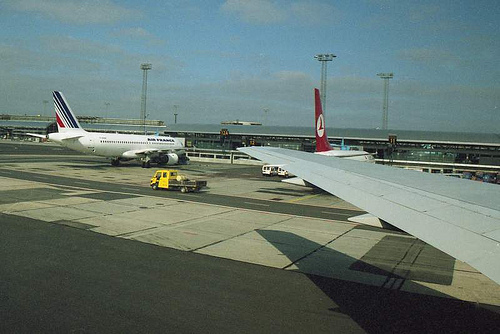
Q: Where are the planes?
A: On the runway.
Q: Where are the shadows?
A: On the ground.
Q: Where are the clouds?
A: In the sky.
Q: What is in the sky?
A: Clouds.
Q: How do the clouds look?
A: Grey.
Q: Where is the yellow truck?
A: Between the planes.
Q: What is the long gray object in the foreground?
A: Wing of airplane.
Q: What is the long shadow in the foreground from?
A: Wing of airplane.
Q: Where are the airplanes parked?
A: Tarmac.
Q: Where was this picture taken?
A: Airport.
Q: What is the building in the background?
A: Airport Terminal.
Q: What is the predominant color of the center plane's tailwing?
A: Red.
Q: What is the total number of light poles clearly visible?
A: 3.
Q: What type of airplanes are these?
A: Passenger Jets.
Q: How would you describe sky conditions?
A: Clear with some clouds.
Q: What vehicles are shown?
A: Airplanes.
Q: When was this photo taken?
A: Daytime.